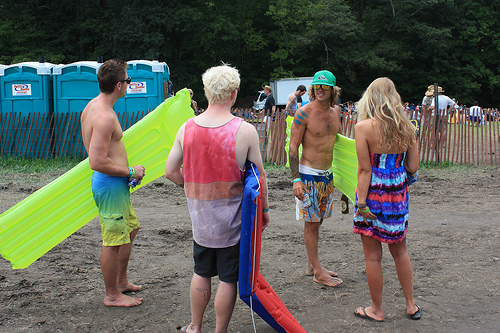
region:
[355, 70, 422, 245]
A girl with long blonde hair.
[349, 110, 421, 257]
A girl in multi colored dress.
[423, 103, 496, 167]
A wooden fence in background.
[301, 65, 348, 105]
A young man in a green hat.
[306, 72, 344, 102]
A pair of sunglasses.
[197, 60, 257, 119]
A young man with blonde hair.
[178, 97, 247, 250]
A pink and grey tank top .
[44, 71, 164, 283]
A man holding a yellow float.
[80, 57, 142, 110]
A dark haired man.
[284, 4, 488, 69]
Trees in the background.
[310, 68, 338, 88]
man is wearing blue hat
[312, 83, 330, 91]
man is wearing goggles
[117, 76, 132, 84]
the man is wearing goggles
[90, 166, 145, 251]
the man is wearing multicolor shorts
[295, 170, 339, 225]
the man is wearing multicolor shorts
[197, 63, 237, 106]
the man's hair is blonde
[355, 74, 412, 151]
the woman's hair is blonde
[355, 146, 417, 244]
the woman is wearing a multicolored dress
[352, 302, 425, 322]
the woman is wearing sandals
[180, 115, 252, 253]
the man is wearing a multicolor tank top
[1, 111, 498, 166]
Wooden fence separating people from portable bathrooms.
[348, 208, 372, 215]
Green bracelet on girl's wrist.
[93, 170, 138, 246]
Blue and yellow shorts worn by brown haired guy.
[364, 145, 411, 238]
Tie dye dress worn by girl.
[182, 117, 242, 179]
Red section of tank top worn by blond guy.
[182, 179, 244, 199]
Brown section of tank top worn by blond haired guy.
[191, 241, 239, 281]
Black shorts worn by blond haired guy.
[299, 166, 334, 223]
Multicolored shorts worn by guy standing in front of girl.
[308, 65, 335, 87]
Hat worn by guy in multicolored shorts.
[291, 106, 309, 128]
Three stripes on arm of guy wearing the hat.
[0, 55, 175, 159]
three porta potties in a row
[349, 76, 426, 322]
a blond girl in a summer dress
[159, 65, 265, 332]
a blond man with a sunburned neck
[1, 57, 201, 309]
a man in sunglasses carries a bright yellow inflatable sunbed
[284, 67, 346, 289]
a man is shirtless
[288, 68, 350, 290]
a shirtless man in a green baseball cap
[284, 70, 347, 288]
a shirtless man with blue paint on his shoulder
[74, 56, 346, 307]
two men are barefoot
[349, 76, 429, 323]
a girl in a sundress wears a green bracelet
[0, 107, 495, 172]
a wooden fence in front of a row of porta potties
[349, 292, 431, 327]
two feet with sandals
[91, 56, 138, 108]
a person with glasses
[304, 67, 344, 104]
a hat on a persons head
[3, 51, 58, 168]
a bathroom behind a fence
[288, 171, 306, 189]
a bracelet on a wrist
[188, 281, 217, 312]
a tattoo on a leg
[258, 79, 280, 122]
a person with a black shirt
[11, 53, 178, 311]
a person holding a raft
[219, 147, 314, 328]
a blue and red raft near a person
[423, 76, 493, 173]
people behind a fence